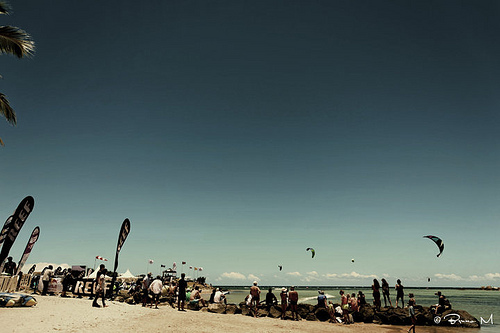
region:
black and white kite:
[417, 230, 448, 258]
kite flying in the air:
[428, 233, 449, 255]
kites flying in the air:
[252, 234, 376, 286]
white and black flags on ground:
[106, 212, 132, 274]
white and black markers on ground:
[0, 191, 47, 253]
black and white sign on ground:
[70, 273, 111, 294]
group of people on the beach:
[233, 275, 450, 331]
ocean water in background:
[451, 286, 484, 310]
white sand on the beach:
[48, 308, 145, 330]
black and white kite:
[425, 231, 448, 258]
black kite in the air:
[423, 231, 450, 254]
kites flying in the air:
[258, 230, 384, 275]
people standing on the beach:
[241, 272, 442, 324]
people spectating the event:
[173, 267, 451, 320]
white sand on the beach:
[57, 316, 169, 331]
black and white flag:
[107, 218, 138, 256]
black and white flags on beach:
[0, 187, 49, 264]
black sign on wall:
[62, 278, 110, 298]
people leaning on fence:
[36, 250, 80, 296]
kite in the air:
[424, 235, 442, 256]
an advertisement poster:
[73, 279, 112, 297]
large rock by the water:
[353, 303, 479, 326]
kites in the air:
[273, 233, 443, 273]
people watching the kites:
[246, 277, 411, 312]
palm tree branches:
[0, 0, 35, 127]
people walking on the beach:
[92, 264, 109, 308]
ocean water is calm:
[223, 284, 497, 319]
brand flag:
[112, 218, 130, 272]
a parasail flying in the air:
[420, 233, 443, 260]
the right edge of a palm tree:
[0, 1, 29, 129]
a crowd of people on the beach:
[252, 240, 457, 324]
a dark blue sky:
[153, 0, 494, 183]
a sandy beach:
[234, 285, 490, 330]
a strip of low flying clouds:
[212, 263, 497, 282]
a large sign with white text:
[65, 278, 120, 299]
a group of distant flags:
[92, 251, 209, 278]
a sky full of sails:
[248, 228, 454, 280]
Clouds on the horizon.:
[214, 268, 497, 285]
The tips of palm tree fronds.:
[0, 1, 37, 126]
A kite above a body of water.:
[420, 233, 447, 257]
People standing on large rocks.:
[368, 276, 410, 309]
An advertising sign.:
[74, 277, 117, 297]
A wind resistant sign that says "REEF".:
[1, 193, 36, 289]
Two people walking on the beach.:
[91, 263, 112, 310]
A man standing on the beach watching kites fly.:
[175, 271, 190, 313]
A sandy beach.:
[2, 286, 494, 331]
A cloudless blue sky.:
[3, 2, 498, 256]